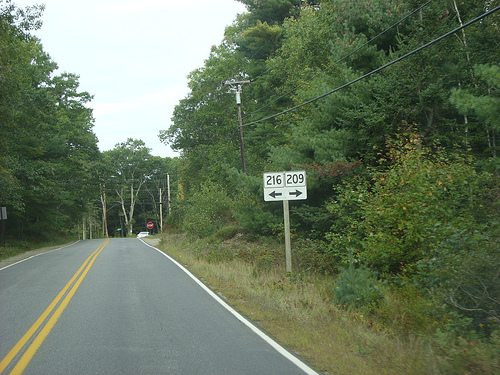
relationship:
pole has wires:
[223, 78, 252, 173] [103, 3, 500, 205]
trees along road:
[0, 0, 498, 373] [1, 235, 324, 373]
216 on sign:
[266, 175, 282, 186] [264, 172, 308, 200]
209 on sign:
[287, 173, 306, 184] [264, 172, 308, 200]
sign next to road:
[264, 172, 308, 200] [1, 235, 324, 373]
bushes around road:
[0, 117, 500, 374] [1, 235, 324, 373]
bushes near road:
[0, 117, 500, 374] [1, 235, 324, 373]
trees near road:
[0, 0, 498, 373] [1, 235, 324, 373]